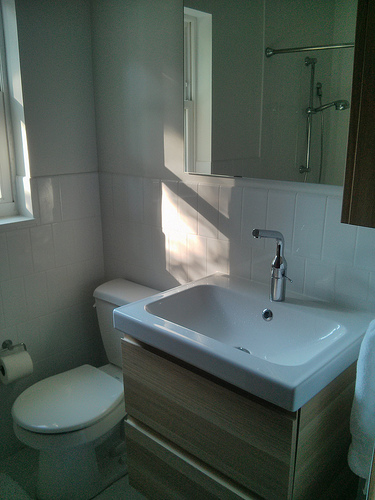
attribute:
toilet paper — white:
[2, 349, 36, 387]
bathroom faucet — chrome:
[253, 225, 288, 300]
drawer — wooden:
[119, 336, 296, 498]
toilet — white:
[9, 273, 169, 498]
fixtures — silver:
[245, 218, 298, 308]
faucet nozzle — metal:
[251, 230, 262, 239]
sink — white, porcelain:
[110, 274, 373, 410]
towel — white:
[348, 315, 371, 475]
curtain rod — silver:
[265, 43, 353, 59]